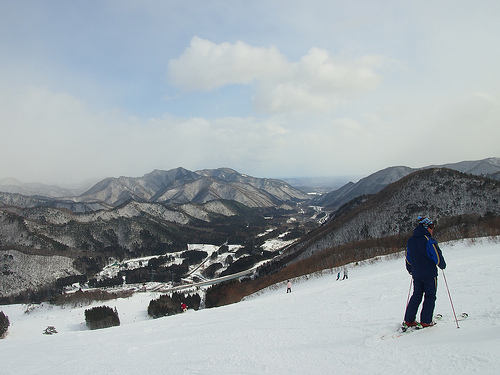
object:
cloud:
[167, 34, 382, 91]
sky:
[1, 1, 499, 188]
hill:
[263, 165, 498, 272]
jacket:
[178, 302, 188, 307]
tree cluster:
[117, 265, 187, 285]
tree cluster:
[224, 251, 266, 273]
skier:
[393, 213, 448, 335]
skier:
[338, 263, 353, 283]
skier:
[333, 263, 343, 281]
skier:
[281, 274, 295, 296]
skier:
[176, 300, 191, 319]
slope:
[1, 231, 498, 373]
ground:
[386, 145, 393, 188]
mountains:
[2, 157, 497, 297]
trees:
[85, 302, 120, 332]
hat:
[416, 214, 440, 227]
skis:
[371, 312, 444, 341]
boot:
[400, 320, 418, 329]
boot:
[417, 320, 435, 327]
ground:
[390, 70, 447, 138]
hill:
[83, 170, 243, 234]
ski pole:
[400, 276, 412, 327]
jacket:
[403, 223, 446, 280]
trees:
[192, 231, 269, 283]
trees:
[39, 287, 133, 307]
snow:
[3, 190, 498, 373]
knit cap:
[417, 217, 432, 230]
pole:
[434, 256, 462, 329]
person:
[402, 212, 447, 338]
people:
[281, 262, 355, 297]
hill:
[102, 245, 495, 375]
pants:
[402, 266, 442, 326]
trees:
[346, 246, 368, 260]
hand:
[402, 256, 449, 276]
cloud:
[265, 81, 345, 131]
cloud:
[168, 122, 299, 165]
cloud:
[51, 83, 134, 133]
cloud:
[358, 27, 462, 87]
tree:
[121, 259, 189, 281]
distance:
[3, 58, 498, 262]